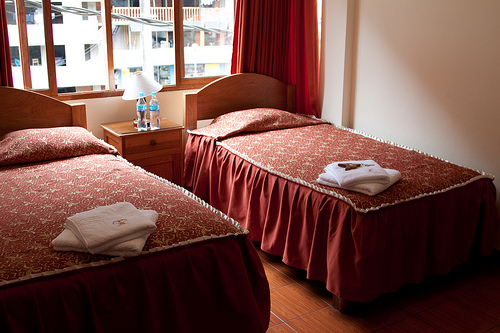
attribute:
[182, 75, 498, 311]
bed — One large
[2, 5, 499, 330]
room —  hotel 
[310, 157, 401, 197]
towels — white, decorated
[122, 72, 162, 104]
shade — white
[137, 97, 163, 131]
bottles — 2, unopened, two water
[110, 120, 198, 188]
table — small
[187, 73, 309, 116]
headboard — wood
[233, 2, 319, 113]
drapes — red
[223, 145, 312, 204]
trim — white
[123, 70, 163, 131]
one lamp — One 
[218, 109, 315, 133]
pillow — red,  red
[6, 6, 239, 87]
windows — large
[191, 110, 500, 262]
blanket — color of root beer, red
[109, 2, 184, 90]
window — large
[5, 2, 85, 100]
window — open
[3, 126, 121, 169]
pillow case — red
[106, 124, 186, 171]
night table — brown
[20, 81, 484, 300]
beds —  twin,  pair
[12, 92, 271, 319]
bed — one small hotel 